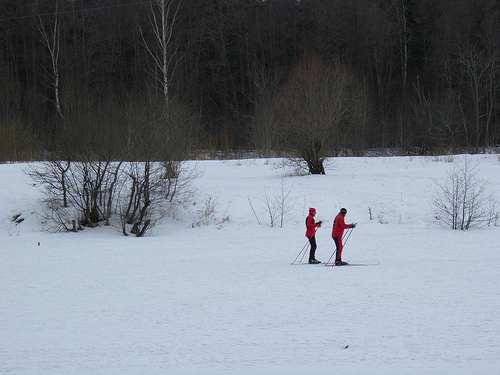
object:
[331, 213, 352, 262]
snowsuit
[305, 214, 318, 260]
snowsuit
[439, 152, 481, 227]
trees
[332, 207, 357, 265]
man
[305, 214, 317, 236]
coat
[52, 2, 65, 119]
tree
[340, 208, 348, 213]
hat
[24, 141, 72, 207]
trees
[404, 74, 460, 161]
short tree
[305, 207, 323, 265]
country skier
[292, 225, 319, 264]
ski pole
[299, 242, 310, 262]
ski pole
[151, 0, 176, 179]
tree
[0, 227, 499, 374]
field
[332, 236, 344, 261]
pants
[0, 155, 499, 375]
snow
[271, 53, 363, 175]
trees